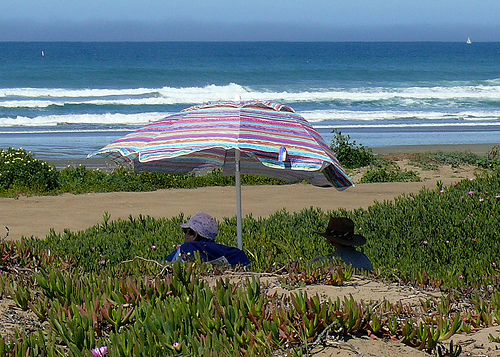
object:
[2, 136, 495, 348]
beach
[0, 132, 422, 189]
plants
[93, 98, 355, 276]
umbrella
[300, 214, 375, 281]
man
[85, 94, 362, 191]
shore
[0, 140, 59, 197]
bush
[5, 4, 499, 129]
ocean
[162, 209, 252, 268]
people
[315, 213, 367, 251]
hat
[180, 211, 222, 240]
hat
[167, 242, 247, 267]
shirt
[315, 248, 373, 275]
shirt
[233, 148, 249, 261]
pole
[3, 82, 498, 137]
waves crashing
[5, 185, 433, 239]
path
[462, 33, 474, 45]
sail boat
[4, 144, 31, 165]
white buds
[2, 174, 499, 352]
plants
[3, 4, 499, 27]
sky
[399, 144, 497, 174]
sand